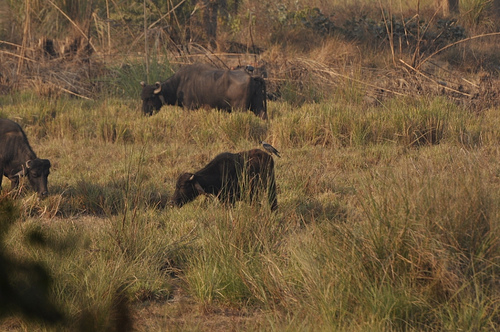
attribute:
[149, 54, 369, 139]
cow — big, black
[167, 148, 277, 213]
animal — brown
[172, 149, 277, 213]
wildebeest — young, grazing 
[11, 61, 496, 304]
grass — green, tall, dry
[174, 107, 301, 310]
tall grass — tall , patch 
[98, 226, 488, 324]
grass — tall, dry, green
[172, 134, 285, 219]
baby steer — baby 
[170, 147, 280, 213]
adult steer — adult 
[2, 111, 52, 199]
adult steer — adult 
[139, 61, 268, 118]
adult steer — adult 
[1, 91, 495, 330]
grasslands — dry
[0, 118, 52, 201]
wildebeest — large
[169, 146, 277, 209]
wildebeest — large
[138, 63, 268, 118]
wildebeest — large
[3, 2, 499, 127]
branches — dry, dead 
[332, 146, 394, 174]
grass — short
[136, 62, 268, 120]
cow — black, big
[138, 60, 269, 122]
steer — adult 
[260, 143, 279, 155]
bird — small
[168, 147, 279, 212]
cow — small, black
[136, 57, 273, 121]
steer — adult 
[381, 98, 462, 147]
landscape — grassy 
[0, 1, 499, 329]
grass — green, tall, dry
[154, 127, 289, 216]
steer — baby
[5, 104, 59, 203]
steer — adult 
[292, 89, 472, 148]
grass — green, tall, dry